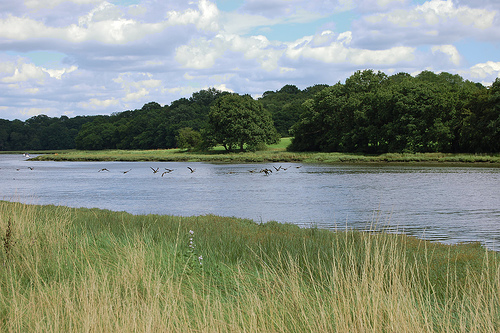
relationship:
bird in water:
[255, 157, 281, 185] [338, 188, 441, 229]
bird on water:
[255, 157, 281, 185] [338, 188, 441, 229]